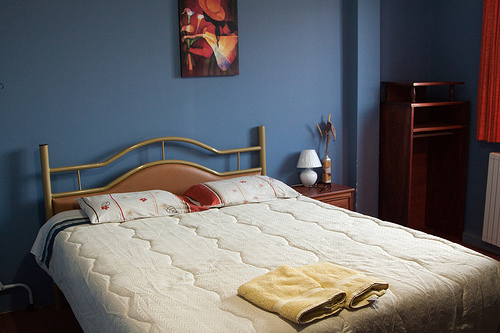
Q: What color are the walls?
A: Blue.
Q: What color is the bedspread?
A: White.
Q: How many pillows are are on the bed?
A: 2.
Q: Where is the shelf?
A: Corner.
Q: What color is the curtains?
A: Orange.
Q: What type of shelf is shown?
A: Wooden.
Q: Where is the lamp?
A: Beside the bed.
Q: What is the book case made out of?
A: Wood.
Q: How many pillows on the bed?
A: Two.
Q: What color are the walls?
A: Blue.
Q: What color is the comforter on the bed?
A: White.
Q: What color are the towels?
A: Yellow.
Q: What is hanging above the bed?
A: Painting.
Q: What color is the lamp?
A: White.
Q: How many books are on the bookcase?
A: 0.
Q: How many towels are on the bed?
A: 2.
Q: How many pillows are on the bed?
A: 2.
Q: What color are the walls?
A: Blue.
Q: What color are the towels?
A: Cream.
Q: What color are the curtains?
A: Orange.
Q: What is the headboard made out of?
A: Metal.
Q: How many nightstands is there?
A: 1.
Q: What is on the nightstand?
A: A lamp and a vase.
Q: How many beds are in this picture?
A: One.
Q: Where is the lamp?
A: Beside the bed.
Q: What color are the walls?
A: Blue.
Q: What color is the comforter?
A: White.